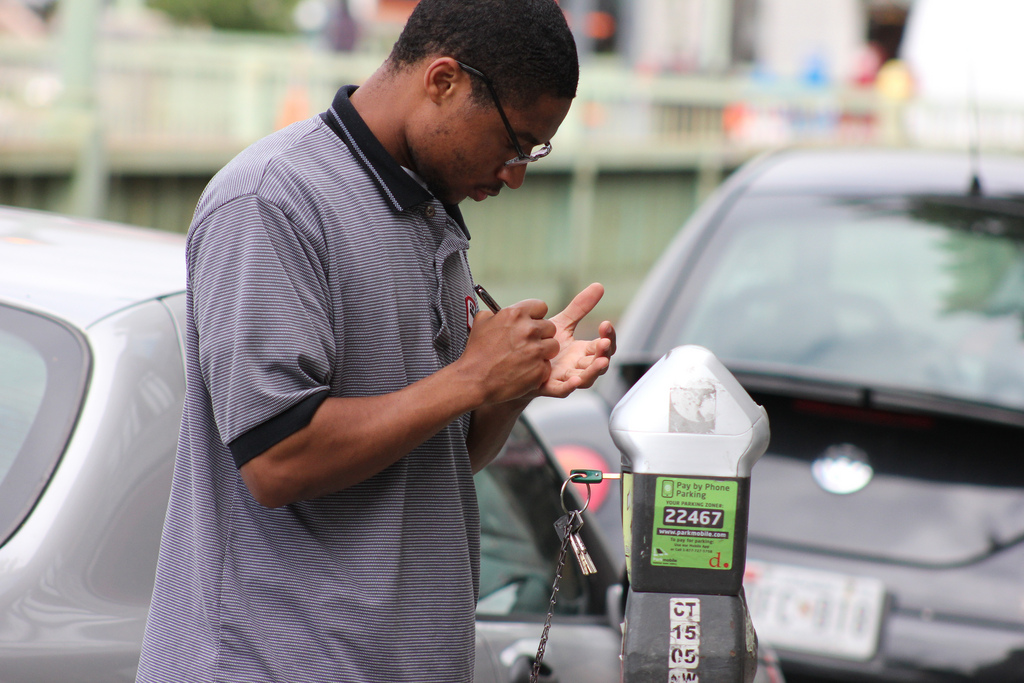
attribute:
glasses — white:
[459, 75, 559, 164]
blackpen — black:
[465, 282, 505, 311]